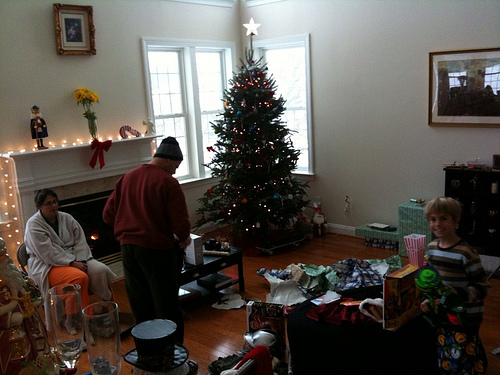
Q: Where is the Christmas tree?
A: In the corner of the room.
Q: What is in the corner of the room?
A: Christmas tree.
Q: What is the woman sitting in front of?
A: Fireplace.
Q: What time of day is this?
A: Daylight hours.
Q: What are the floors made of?
A: Hardwood floors.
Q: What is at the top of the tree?
A: Star.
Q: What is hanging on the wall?
A: Framed pictures.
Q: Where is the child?
A: Far right.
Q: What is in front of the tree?
A: Gifts.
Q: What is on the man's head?
A: Black hat.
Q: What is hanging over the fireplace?
A: Red bow.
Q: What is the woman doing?
A: Sitting on a chair.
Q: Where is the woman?
A: In the living room.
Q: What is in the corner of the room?
A: A decorated Christmas tree.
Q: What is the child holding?
A: A toy.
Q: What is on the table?
A: Champagne flutes.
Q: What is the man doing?
A: Standing.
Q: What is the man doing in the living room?
A: Opening gifts.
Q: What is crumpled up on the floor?
A: Wrapping paper.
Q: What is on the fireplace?
A: A vase with orange flowers.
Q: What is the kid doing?
A: Smiling at the camera.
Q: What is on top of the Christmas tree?
A: A star.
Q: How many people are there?
A: Three.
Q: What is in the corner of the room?
A: A Christmas tree.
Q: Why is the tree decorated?
A: It's tradition.